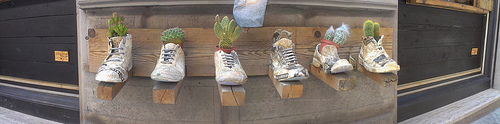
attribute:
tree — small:
[211, 14, 242, 51]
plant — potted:
[211, 11, 241, 48]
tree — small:
[161, 26, 186, 42]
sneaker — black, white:
[268, 38, 307, 80]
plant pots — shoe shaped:
[203, 38, 257, 95]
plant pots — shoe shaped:
[356, 21, 404, 87]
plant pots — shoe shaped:
[307, 32, 355, 84]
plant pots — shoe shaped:
[259, 34, 306, 94]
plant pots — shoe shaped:
[147, 35, 193, 94]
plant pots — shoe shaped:
[89, 27, 140, 86]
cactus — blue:
[309, 16, 354, 47]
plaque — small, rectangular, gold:
[56, 49, 69, 63]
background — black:
[2, 0, 493, 112]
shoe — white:
[77, 16, 462, 104]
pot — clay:
[343, 14, 433, 94]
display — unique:
[83, 23, 403, 121]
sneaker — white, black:
[308, 40, 350, 80]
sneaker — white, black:
[352, 32, 399, 72]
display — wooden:
[84, 12, 402, 95]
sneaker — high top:
[94, 34, 137, 85]